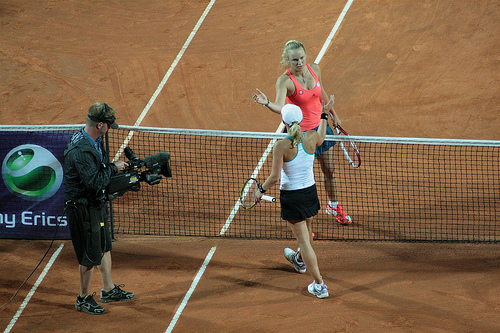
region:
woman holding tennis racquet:
[240, 33, 366, 254]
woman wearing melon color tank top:
[240, 25, 357, 257]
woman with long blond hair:
[249, 30, 322, 165]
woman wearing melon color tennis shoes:
[301, 162, 362, 234]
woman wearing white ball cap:
[242, 95, 337, 309]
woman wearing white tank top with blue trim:
[224, 63, 356, 322]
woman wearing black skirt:
[201, 69, 382, 302]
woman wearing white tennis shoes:
[228, 84, 356, 314]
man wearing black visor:
[45, 74, 156, 322]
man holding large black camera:
[24, 44, 191, 311]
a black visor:
[87, 106, 121, 131]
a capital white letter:
[20, 207, 33, 227]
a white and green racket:
[230, 175, 283, 210]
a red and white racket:
[332, 118, 362, 170]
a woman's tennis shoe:
[305, 273, 334, 300]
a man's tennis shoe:
[98, 286, 140, 298]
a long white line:
[2, 0, 214, 331]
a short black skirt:
[279, 183, 324, 221]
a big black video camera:
[95, 145, 176, 195]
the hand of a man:
[115, 161, 127, 171]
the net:
[371, 133, 465, 293]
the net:
[411, 147, 436, 252]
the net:
[414, 159, 436, 216]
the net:
[364, 176, 432, 236]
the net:
[371, 122, 424, 204]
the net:
[434, 140, 484, 240]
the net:
[416, 148, 463, 270]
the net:
[389, 159, 416, 215]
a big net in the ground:
[110, 128, 498, 243]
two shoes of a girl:
[285, 250, 325, 300]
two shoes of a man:
[56, 290, 138, 315]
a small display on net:
[4, 133, 102, 227]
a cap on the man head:
[68, 97, 133, 128]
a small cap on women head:
[280, 95, 296, 125]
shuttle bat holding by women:
[240, 173, 276, 214]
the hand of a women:
[248, 83, 283, 115]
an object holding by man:
[123, 146, 173, 187]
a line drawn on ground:
[142, 0, 220, 125]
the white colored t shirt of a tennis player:
[265, 129, 332, 195]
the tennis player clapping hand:
[252, 96, 355, 306]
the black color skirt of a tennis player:
[272, 183, 334, 225]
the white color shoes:
[276, 236, 337, 301]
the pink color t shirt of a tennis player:
[276, 65, 336, 136]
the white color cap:
[275, 101, 305, 126]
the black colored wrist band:
[313, 111, 338, 122]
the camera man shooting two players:
[49, 71, 191, 325]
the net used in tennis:
[168, 113, 253, 252]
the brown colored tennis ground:
[195, 268, 287, 328]